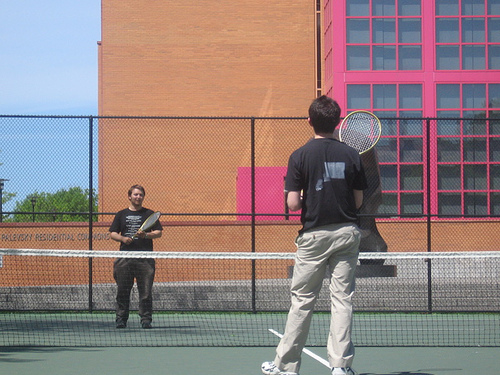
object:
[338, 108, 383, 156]
racket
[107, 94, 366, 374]
players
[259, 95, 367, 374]
boy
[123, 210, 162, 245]
racket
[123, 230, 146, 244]
hands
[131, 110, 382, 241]
racket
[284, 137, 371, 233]
shirt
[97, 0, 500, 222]
building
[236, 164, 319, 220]
building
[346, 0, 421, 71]
window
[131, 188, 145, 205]
face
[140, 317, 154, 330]
shoe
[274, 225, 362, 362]
pants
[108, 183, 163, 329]
man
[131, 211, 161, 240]
racket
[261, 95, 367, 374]
man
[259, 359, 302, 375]
shoe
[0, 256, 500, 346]
net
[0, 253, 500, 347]
fence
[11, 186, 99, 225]
tree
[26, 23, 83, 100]
sky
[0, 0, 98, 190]
sky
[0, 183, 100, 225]
trees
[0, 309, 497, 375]
ground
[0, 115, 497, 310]
fence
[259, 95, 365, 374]
person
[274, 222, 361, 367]
pants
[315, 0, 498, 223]
building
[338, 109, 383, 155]
tennis racket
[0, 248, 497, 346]
tennis net